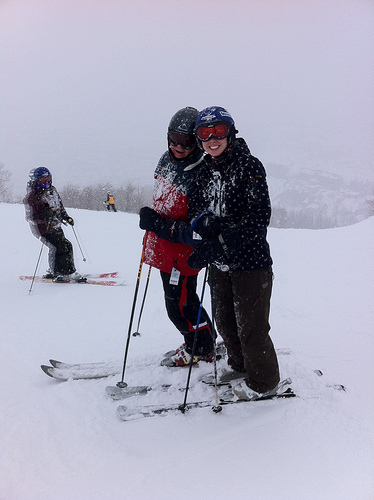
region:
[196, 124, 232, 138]
red goggles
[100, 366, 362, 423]
two skiis on the snow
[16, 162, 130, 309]
person skiing on the snow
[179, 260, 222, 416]
pair of ski poles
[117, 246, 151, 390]
two ski poles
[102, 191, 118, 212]
person wearing a yellow coat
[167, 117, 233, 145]
two goggles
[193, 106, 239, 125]
blue head gear with a white design on it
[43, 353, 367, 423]
four skis covered with snow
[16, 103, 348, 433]
four skiers in the snow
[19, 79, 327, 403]
Skiers.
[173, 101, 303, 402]
The woman is wearing dark clothing.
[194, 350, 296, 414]
Gray boots.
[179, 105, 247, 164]
The woman is wearing a blue helmet.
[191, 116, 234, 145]
The googles are red and black.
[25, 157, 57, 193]
The person is wearing a blue helmet.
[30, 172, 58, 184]
The goggles are orange.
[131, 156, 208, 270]
The jacket is red and black.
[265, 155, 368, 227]
A snow covered mountain.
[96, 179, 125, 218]
A person in a yellow and black clothing.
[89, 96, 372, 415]
two people are skiing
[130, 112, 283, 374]
two people are skiing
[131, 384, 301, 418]
The skis are black.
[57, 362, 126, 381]
The skis are snow covered.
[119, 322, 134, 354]
The ski poles are black.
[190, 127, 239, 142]
Woman is wearing red goggles.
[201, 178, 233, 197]
Snow on the jacket.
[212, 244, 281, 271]
Polka dots on the jacket.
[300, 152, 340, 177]
Snow on the ground.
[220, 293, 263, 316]
The pants are brown.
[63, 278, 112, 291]
The skis are red.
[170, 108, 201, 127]
The man's helmet is black.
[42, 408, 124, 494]
the snow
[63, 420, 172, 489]
the snow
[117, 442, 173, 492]
the snow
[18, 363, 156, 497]
the snow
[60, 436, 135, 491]
the snow